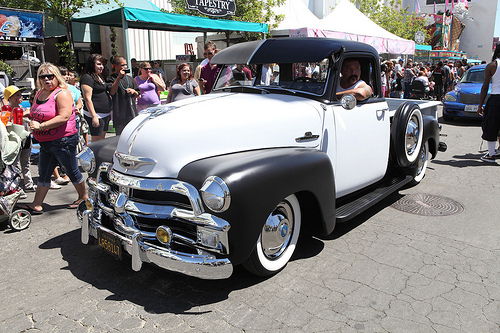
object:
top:
[28, 90, 78, 140]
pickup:
[87, 38, 442, 283]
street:
[0, 81, 498, 330]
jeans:
[37, 140, 87, 185]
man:
[337, 58, 374, 101]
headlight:
[198, 178, 229, 215]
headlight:
[74, 145, 95, 173]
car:
[446, 60, 499, 119]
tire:
[394, 106, 424, 164]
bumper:
[76, 166, 230, 280]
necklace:
[115, 75, 130, 90]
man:
[108, 55, 135, 137]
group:
[82, 39, 246, 134]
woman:
[32, 52, 109, 234]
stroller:
[2, 105, 41, 253]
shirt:
[25, 80, 81, 137]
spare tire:
[392, 99, 423, 169]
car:
[77, 37, 437, 287]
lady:
[15, 60, 90, 217]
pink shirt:
[27, 85, 79, 144]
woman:
[77, 51, 121, 171]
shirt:
[79, 70, 117, 112]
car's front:
[72, 140, 236, 281]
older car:
[77, 33, 448, 281]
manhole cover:
[395, 184, 470, 226]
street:
[276, 171, 490, 330]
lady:
[165, 60, 204, 105]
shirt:
[165, 77, 201, 101]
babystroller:
[0, 121, 46, 231]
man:
[474, 44, 499, 163]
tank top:
[488, 58, 499, 93]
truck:
[108, 34, 448, 277]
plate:
[91, 227, 125, 257]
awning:
[68, 0, 268, 37]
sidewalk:
[106, 130, 115, 140]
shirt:
[106, 66, 139, 118]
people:
[87, 55, 194, 95]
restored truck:
[82, 37, 444, 278]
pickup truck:
[76, 35, 448, 284]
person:
[415, 70, 435, 95]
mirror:
[339, 90, 359, 112]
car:
[438, 59, 498, 124]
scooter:
[400, 73, 444, 113]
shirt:
[130, 69, 166, 115]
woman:
[124, 54, 164, 129]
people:
[19, 40, 255, 164]